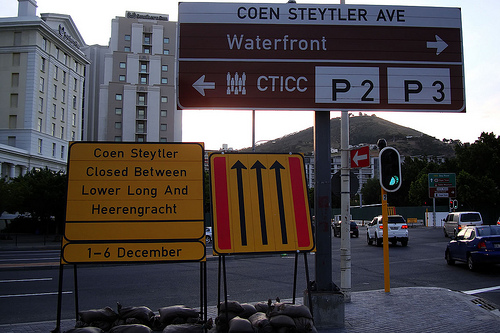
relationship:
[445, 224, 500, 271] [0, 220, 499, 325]
car on street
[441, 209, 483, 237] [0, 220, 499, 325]
car on street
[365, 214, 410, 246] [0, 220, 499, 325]
car on street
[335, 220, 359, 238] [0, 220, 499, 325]
car on street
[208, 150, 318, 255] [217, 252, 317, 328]
sign on post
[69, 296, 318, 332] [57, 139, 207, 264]
sandbags holding sign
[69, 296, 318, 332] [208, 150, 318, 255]
sandbags holding sign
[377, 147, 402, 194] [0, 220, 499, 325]
traffic light near street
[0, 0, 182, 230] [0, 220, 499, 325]
building near street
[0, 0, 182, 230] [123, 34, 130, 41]
building has window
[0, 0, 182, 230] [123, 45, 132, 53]
building has window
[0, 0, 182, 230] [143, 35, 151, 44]
building has window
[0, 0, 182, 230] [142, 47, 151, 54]
building has window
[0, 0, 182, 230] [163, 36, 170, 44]
building has window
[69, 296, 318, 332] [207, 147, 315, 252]
sandbags holding signs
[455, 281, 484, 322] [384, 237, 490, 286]
drainage on street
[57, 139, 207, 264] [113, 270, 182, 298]
sign adjacent a street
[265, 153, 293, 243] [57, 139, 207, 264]
black arrow on sign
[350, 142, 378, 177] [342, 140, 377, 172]
arrow on sign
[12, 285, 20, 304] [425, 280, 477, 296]
lines painted asphalt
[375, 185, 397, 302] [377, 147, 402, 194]
yellow post on traffic light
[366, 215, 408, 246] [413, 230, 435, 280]
vehicle on street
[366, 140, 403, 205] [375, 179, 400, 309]
signal on pole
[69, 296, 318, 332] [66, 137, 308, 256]
sandbags on sign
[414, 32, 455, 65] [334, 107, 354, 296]
arrow on pole